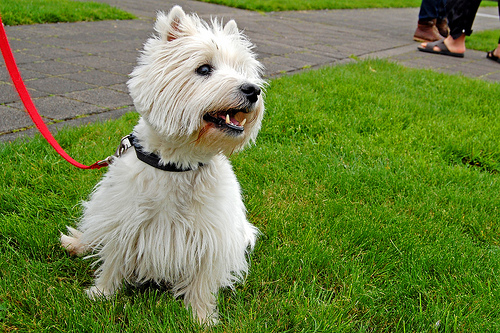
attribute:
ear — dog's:
[219, 4, 244, 38]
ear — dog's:
[150, 7, 201, 43]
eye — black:
[159, 60, 243, 107]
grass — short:
[3, 2, 134, 23]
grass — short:
[222, 3, 498, 9]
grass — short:
[457, 30, 499, 52]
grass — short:
[3, 60, 497, 331]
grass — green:
[293, 107, 467, 287]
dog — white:
[50, 4, 320, 329]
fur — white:
[51, 2, 273, 329]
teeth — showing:
[237, 117, 247, 128]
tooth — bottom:
[223, 115, 253, 128]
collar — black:
[114, 124, 235, 194]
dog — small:
[45, 6, 270, 331]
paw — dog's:
[179, 280, 231, 330]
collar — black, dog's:
[126, 131, 205, 174]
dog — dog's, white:
[52, 0, 297, 330]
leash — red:
[1, 22, 114, 170]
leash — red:
[0, 12, 135, 168]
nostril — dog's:
[231, 75, 263, 108]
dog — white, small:
[61, 3, 261, 327]